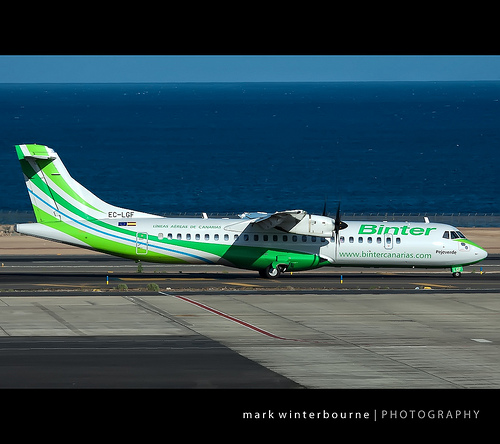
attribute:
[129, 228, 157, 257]
door — rear, passenger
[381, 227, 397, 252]
door — front passenger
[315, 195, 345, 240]
propellers — black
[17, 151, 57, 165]
stabilizer — horizontal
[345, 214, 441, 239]
name — green, plane's company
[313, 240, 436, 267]
email address — plane's company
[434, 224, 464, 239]
windows — side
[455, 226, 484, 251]
airport runway — airports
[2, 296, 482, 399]
runway — airport's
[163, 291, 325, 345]
line — red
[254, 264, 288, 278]
landing gear — rear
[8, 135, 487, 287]
plane — white, green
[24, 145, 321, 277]
stripes — green, blue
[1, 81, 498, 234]
water — blue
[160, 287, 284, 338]
line — red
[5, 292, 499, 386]
runway — grey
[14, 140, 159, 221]
plane tail — green, white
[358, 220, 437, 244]
binter — green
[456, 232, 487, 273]
nose — white, green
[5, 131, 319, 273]
stripes — green, blue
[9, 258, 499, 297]
strip — darker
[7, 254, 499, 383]
runway — grey cement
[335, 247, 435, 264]
website url — company's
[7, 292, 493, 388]
ground — grey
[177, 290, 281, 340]
line — red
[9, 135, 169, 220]
tail — bent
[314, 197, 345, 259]
propellers — black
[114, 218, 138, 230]
flag — red, white, blue